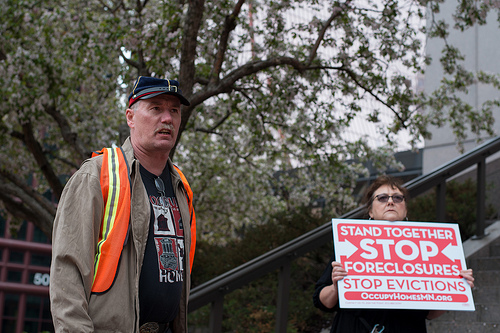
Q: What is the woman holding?
A: A sign.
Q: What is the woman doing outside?
A: Protesting.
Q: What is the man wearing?
A: A safety vest.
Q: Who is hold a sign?
A: The woman.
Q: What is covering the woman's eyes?
A: The woman's sunglasses.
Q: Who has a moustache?
A: The man.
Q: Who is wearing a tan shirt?
A: The man.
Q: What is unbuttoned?
A: The tan shirt.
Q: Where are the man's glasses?
A: Hooked over neck of shirt.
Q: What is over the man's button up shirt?
A: Safety vest.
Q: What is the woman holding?
A: Sign.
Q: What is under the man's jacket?
A: Black shirt.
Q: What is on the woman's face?
A: Sunglasses.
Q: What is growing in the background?
A: Tree.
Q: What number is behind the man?
A: 50.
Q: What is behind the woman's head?
A: Rail.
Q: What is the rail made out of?
A: Metal.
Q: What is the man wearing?
A: A khaki shirt with an orange vest and black hat.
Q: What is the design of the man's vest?
A: The vest is orange and yellow vest.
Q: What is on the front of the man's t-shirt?
A: An outline of a house.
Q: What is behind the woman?
A: A black iron railing.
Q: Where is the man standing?
A: In front of a mature tree.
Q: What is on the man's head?
A: A black hat with red trim.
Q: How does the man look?
A: He is approximately 5'8", pale skin, a grayish mustache and he is of European descent.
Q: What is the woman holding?
A: A sign advocating for the cessation of foreclosures and evictions.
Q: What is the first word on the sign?
A: Stand.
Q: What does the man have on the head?
A: Hat.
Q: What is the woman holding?
A: A sign.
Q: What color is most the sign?
A: Red.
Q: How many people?
A: Two.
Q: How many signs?
A: One.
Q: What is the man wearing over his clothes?
A: A vest.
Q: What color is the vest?
A: Orange.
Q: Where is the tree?
A: Behind the people.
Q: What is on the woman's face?
A: Glasses.